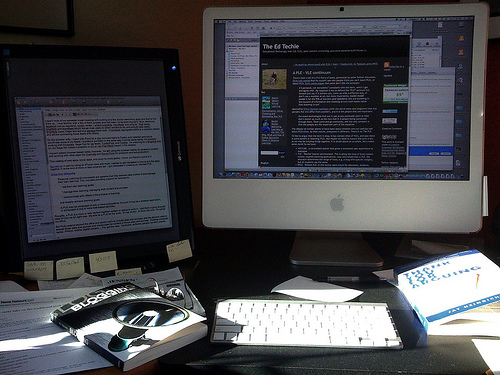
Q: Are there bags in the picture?
A: No, there are no bags.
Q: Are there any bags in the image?
A: No, there are no bags.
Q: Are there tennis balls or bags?
A: No, there are no bags or tennis balls.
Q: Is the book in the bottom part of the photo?
A: Yes, the book is in the bottom of the image.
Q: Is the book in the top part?
A: No, the book is in the bottom of the image.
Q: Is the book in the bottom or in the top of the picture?
A: The book is in the bottom of the image.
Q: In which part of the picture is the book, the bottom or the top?
A: The book is in the bottom of the image.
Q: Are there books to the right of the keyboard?
A: Yes, there is a book to the right of the keyboard.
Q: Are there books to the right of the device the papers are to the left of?
A: Yes, there is a book to the right of the keyboard.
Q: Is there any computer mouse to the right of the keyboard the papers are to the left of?
A: No, there is a book to the right of the keyboard.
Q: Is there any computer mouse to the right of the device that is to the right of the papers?
A: No, there is a book to the right of the keyboard.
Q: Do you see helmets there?
A: No, there are no helmets.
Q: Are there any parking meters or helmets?
A: No, there are no helmets or parking meters.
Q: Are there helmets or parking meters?
A: No, there are no helmets or parking meters.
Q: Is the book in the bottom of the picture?
A: Yes, the book is in the bottom of the image.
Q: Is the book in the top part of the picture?
A: No, the book is in the bottom of the image.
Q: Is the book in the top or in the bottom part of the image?
A: The book is in the bottom of the image.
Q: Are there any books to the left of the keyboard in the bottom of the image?
A: Yes, there is a book to the left of the keyboard.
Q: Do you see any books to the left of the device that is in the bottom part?
A: Yes, there is a book to the left of the keyboard.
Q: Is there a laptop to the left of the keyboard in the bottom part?
A: No, there is a book to the left of the keyboard.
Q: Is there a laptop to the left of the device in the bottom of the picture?
A: No, there is a book to the left of the keyboard.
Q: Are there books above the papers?
A: Yes, there is a book above the papers.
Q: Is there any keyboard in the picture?
A: Yes, there is a keyboard.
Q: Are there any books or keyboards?
A: Yes, there is a keyboard.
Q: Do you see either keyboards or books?
A: Yes, there is a keyboard.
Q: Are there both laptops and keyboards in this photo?
A: No, there is a keyboard but no laptops.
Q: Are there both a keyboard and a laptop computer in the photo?
A: No, there is a keyboard but no laptops.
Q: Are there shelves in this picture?
A: No, there are no shelves.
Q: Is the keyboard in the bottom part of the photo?
A: Yes, the keyboard is in the bottom of the image.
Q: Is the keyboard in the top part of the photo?
A: No, the keyboard is in the bottom of the image.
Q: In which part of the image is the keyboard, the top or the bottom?
A: The keyboard is in the bottom of the image.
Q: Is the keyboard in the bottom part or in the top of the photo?
A: The keyboard is in the bottom of the image.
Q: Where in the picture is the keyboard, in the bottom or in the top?
A: The keyboard is in the bottom of the image.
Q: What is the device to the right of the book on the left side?
A: The device is a keyboard.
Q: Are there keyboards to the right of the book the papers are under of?
A: Yes, there is a keyboard to the right of the book.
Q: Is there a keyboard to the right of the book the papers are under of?
A: Yes, there is a keyboard to the right of the book.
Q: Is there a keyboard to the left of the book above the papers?
A: No, the keyboard is to the right of the book.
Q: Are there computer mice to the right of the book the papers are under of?
A: No, there is a keyboard to the right of the book.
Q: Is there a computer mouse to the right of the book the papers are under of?
A: No, there is a keyboard to the right of the book.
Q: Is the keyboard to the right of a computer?
A: No, the keyboard is to the right of a book.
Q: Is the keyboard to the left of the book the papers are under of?
A: No, the keyboard is to the right of the book.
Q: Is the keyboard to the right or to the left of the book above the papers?
A: The keyboard is to the right of the book.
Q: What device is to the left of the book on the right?
A: The device is a keyboard.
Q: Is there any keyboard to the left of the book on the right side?
A: Yes, there is a keyboard to the left of the book.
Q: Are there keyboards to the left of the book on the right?
A: Yes, there is a keyboard to the left of the book.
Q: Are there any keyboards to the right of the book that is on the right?
A: No, the keyboard is to the left of the book.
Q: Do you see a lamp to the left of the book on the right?
A: No, there is a keyboard to the left of the book.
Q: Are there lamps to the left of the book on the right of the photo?
A: No, there is a keyboard to the left of the book.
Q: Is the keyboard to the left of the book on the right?
A: Yes, the keyboard is to the left of the book.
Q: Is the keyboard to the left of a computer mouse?
A: No, the keyboard is to the left of the book.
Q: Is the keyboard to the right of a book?
A: No, the keyboard is to the left of a book.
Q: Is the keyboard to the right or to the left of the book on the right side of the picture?
A: The keyboard is to the left of the book.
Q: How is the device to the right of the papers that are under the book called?
A: The device is a keyboard.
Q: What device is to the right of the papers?
A: The device is a keyboard.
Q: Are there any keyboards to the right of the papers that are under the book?
A: Yes, there is a keyboard to the right of the papers.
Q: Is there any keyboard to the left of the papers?
A: No, the keyboard is to the right of the papers.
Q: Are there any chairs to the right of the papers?
A: No, there is a keyboard to the right of the papers.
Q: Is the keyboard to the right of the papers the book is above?
A: Yes, the keyboard is to the right of the papers.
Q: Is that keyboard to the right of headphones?
A: No, the keyboard is to the right of the papers.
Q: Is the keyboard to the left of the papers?
A: No, the keyboard is to the right of the papers.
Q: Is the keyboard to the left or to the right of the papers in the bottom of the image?
A: The keyboard is to the right of the papers.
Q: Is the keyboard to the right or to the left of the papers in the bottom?
A: The keyboard is to the right of the papers.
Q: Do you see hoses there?
A: No, there are no hoses.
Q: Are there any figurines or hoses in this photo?
A: No, there are no hoses or figurines.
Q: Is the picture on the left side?
A: Yes, the picture is on the left of the image.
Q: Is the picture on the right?
A: No, the picture is on the left of the image.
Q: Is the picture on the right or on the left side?
A: The picture is on the left of the image.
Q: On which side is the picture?
A: The picture is on the left of the image.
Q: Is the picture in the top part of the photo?
A: Yes, the picture is in the top of the image.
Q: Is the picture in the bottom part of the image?
A: No, the picture is in the top of the image.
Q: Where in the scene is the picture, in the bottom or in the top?
A: The picture is in the top of the image.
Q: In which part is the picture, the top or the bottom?
A: The picture is in the top of the image.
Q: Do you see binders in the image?
A: No, there are no binders.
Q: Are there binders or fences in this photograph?
A: No, there are no binders or fences.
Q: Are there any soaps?
A: No, there are no soaps.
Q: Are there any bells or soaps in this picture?
A: No, there are no soaps or bells.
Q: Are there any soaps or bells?
A: No, there are no soaps or bells.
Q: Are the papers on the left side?
A: Yes, the papers are on the left of the image.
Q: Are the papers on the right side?
A: No, the papers are on the left of the image.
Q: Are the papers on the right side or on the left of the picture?
A: The papers are on the left of the image.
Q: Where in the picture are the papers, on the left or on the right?
A: The papers are on the left of the image.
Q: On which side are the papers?
A: The papers are on the left of the image.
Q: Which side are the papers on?
A: The papers are on the left of the image.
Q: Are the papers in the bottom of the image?
A: Yes, the papers are in the bottom of the image.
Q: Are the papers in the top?
A: No, the papers are in the bottom of the image.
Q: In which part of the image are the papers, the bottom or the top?
A: The papers are in the bottom of the image.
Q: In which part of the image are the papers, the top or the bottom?
A: The papers are in the bottom of the image.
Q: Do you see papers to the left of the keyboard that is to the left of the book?
A: Yes, there are papers to the left of the keyboard.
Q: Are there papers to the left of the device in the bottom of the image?
A: Yes, there are papers to the left of the keyboard.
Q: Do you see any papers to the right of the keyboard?
A: No, the papers are to the left of the keyboard.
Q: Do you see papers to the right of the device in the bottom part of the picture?
A: No, the papers are to the left of the keyboard.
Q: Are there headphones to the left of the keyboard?
A: No, there are papers to the left of the keyboard.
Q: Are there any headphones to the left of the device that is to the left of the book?
A: No, there are papers to the left of the keyboard.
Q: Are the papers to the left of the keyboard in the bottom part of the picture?
A: Yes, the papers are to the left of the keyboard.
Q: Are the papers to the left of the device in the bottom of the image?
A: Yes, the papers are to the left of the keyboard.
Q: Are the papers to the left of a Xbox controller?
A: No, the papers are to the left of the keyboard.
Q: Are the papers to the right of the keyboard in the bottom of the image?
A: No, the papers are to the left of the keyboard.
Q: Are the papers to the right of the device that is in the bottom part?
A: No, the papers are to the left of the keyboard.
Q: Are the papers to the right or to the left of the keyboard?
A: The papers are to the left of the keyboard.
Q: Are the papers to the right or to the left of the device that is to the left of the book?
A: The papers are to the left of the keyboard.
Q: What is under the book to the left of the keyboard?
A: The papers are under the book.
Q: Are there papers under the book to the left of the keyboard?
A: Yes, there are papers under the book.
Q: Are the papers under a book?
A: Yes, the papers are under a book.